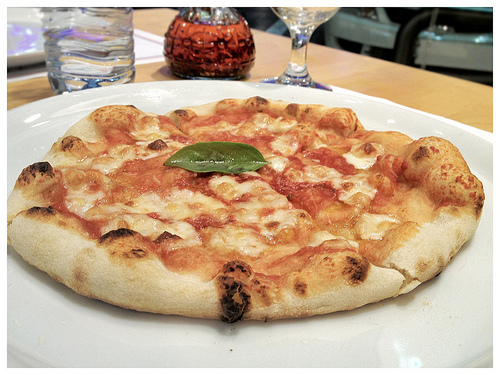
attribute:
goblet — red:
[164, 9, 256, 79]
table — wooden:
[356, 46, 497, 130]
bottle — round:
[161, 8, 261, 82]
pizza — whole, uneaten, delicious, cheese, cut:
[8, 95, 483, 322]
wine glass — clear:
[267, 8, 337, 88]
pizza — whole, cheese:
[19, 97, 429, 311]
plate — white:
[6, 80, 494, 374]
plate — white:
[37, 84, 487, 361]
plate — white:
[13, 85, 499, 345]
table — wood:
[352, 55, 393, 92]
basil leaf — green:
[162, 141, 272, 174]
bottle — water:
[43, 15, 132, 82]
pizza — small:
[15, 103, 495, 344]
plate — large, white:
[7, 275, 499, 365]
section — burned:
[217, 281, 252, 324]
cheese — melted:
[53, 109, 413, 266]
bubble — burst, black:
[215, 264, 248, 326]